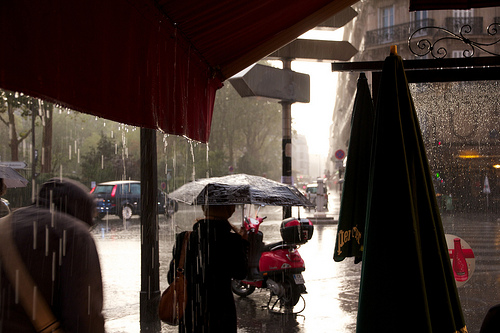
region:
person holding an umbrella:
[156, 156, 318, 222]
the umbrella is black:
[158, 169, 346, 222]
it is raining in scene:
[10, 109, 187, 300]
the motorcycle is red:
[253, 237, 313, 311]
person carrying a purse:
[147, 245, 219, 327]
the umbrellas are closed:
[320, 63, 461, 326]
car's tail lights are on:
[88, 157, 165, 225]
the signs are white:
[240, 39, 394, 114]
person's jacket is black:
[193, 225, 250, 327]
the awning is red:
[3, 0, 274, 125]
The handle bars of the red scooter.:
[235, 210, 269, 229]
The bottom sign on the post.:
[234, 59, 313, 104]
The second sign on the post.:
[263, 34, 373, 67]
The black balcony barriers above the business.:
[366, 19, 498, 51]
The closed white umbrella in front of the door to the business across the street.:
[481, 169, 493, 201]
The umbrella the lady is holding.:
[164, 171, 324, 223]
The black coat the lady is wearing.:
[180, 217, 245, 329]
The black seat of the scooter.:
[256, 230, 288, 250]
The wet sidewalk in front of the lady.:
[121, 198, 351, 330]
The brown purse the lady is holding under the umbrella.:
[156, 220, 186, 321]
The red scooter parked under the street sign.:
[234, 201, 322, 313]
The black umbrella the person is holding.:
[167, 171, 309, 215]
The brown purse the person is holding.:
[154, 230, 194, 326]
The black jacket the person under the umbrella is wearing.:
[174, 215, 261, 327]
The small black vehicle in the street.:
[85, 169, 177, 217]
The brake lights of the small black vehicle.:
[84, 183, 122, 195]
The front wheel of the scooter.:
[226, 269, 249, 294]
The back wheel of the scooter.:
[263, 283, 309, 312]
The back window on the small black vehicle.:
[89, 176, 114, 202]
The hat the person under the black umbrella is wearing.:
[197, 205, 244, 222]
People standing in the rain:
[10, 5, 491, 332]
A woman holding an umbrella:
[163, 166, 323, 228]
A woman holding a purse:
[153, 178, 245, 331]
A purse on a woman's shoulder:
[156, 216, 198, 323]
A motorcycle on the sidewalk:
[223, 214, 318, 321]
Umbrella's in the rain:
[338, 37, 470, 332]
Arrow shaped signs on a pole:
[227, 4, 372, 103]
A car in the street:
[84, 169, 194, 222]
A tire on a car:
[119, 205, 134, 219]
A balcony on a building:
[359, 8, 492, 57]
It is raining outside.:
[53, 117, 267, 223]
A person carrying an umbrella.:
[169, 164, 293, 247]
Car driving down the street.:
[81, 168, 179, 223]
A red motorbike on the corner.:
[235, 219, 317, 309]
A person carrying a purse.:
[147, 232, 194, 321]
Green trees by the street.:
[205, 112, 284, 183]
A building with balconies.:
[344, 5, 499, 47]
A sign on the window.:
[428, 216, 480, 287]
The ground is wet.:
[87, 214, 174, 303]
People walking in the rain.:
[21, 171, 308, 318]